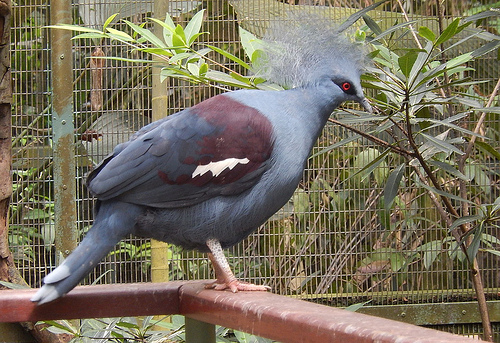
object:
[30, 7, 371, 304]
bird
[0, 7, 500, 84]
weather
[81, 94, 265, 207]
wing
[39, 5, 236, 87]
leaves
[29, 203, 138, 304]
tail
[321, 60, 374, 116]
head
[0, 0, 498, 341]
cage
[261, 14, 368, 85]
hair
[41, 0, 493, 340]
plant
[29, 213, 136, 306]
feather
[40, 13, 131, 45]
foliage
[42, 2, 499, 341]
tree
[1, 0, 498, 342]
enclosure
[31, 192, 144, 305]
tail feathers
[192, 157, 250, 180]
feather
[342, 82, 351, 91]
eye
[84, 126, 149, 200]
feather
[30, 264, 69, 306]
feather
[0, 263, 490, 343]
porch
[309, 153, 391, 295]
fence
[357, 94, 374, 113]
beak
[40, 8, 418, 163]
branches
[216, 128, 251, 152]
part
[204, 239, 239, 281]
back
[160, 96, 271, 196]
feathers